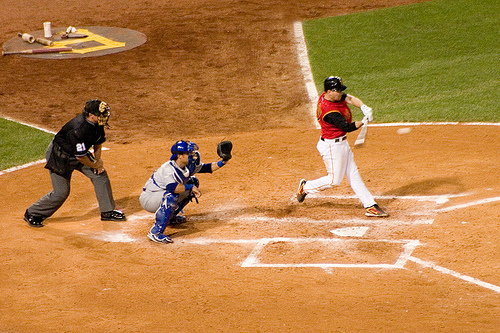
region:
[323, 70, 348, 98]
shiny black baseball headgear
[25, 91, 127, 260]
baseball umpire dressed in black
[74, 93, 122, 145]
umpire's black safety mask and helmet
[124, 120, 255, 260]
baseball catcher in blue and grey uniform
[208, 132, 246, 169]
black catcher's mitt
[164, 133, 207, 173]
blue catcher's safety helmet and mask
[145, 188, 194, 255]
catcher's blue shin guards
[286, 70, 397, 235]
baseball player in red, black and white uniform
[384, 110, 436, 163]
baseball in mid air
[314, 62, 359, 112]
batter's black safety helmet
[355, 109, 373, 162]
baseball bat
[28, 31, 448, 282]
Ground is brown and green color.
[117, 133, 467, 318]
White lines in ground.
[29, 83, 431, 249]
Players are playing baseball.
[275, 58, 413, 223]
Batter is trying to hit the ball.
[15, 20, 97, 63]
Baseball bats in the ground.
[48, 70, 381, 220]
Players are wearing helmet.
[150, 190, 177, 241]
Baseball Catcher Leg Guard is blue color.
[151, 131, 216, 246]
Catcher helmet is blue color.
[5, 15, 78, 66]
Bats are brown color.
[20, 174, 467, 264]
Shadow falls on ground.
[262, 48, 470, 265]
a man in red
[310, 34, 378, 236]
a man in red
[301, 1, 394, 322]
a man in red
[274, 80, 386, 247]
a man in red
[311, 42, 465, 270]
a man in white pants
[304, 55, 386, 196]
a man in white pants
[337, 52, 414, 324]
a man in white pants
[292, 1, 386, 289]
a man in white pants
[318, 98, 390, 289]
a man in white pants